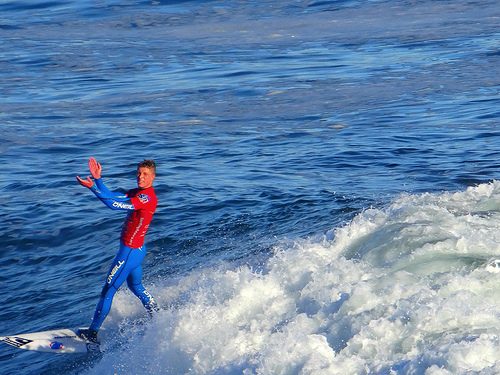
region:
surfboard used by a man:
[8, 318, 201, 356]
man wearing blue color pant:
[89, 240, 150, 333]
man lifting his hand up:
[66, 150, 128, 216]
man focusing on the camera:
[119, 160, 171, 232]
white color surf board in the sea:
[3, 330, 117, 350]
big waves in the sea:
[242, 149, 484, 352]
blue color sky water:
[77, 34, 448, 131]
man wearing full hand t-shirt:
[97, 184, 159, 256]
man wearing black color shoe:
[78, 326, 99, 341]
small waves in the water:
[77, 20, 442, 151]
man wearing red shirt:
[75, 150, 164, 339]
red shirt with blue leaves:
[70, 143, 160, 252]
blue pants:
[84, 244, 167, 348]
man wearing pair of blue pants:
[75, 145, 167, 342]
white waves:
[221, 159, 491, 339]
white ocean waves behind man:
[59, 153, 497, 335]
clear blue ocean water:
[188, 124, 309, 215]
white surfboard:
[0, 319, 137, 360]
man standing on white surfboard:
[9, 152, 188, 362]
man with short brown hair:
[131, 158, 155, 193]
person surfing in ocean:
[2, 125, 208, 373]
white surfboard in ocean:
[2, 322, 141, 358]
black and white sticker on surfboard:
[0, 333, 36, 350]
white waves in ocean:
[112, 182, 489, 374]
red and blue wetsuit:
[75, 174, 162, 345]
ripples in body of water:
[213, 118, 361, 158]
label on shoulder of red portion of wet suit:
[136, 190, 151, 206]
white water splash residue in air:
[147, 245, 245, 317]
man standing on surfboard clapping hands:
[52, 137, 174, 350]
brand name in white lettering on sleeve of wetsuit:
[107, 196, 139, 211]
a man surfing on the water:
[34, 47, 426, 373]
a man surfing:
[36, 119, 222, 372]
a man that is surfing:
[64, 108, 279, 370]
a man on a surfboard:
[1, 93, 293, 372]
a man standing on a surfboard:
[39, 119, 280, 369]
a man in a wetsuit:
[68, 113, 235, 371]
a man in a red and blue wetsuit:
[47, 138, 209, 333]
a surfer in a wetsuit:
[62, 144, 204, 326]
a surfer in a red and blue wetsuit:
[72, 119, 225, 357]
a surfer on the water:
[50, 95, 225, 373]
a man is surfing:
[11, 130, 191, 360]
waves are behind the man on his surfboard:
[167, 179, 493, 369]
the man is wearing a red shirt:
[121, 183, 154, 249]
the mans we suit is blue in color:
[85, 185, 160, 333]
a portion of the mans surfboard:
[10, 306, 157, 356]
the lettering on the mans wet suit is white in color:
[97, 190, 155, 324]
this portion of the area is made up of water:
[18, 17, 444, 154]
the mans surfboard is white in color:
[2, 327, 178, 359]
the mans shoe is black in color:
[74, 318, 118, 350]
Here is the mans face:
[126, 157, 158, 191]